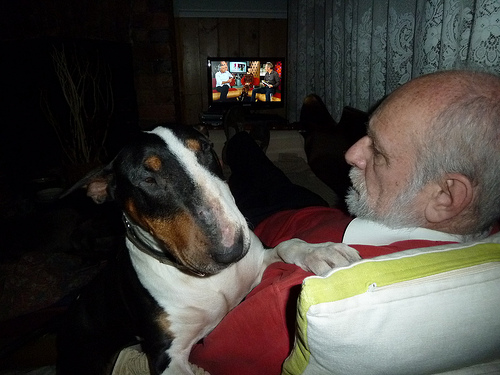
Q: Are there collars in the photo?
A: Yes, there is a collar.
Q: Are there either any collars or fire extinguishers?
A: Yes, there is a collar.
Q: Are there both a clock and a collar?
A: No, there is a collar but no clocks.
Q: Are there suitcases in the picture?
A: No, there are no suitcases.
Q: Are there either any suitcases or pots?
A: No, there are no suitcases or pots.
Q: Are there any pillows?
A: Yes, there is a pillow.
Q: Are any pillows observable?
A: Yes, there is a pillow.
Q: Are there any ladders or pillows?
A: Yes, there is a pillow.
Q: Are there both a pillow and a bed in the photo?
A: No, there is a pillow but no beds.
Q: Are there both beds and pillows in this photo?
A: No, there is a pillow but no beds.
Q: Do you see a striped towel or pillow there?
A: Yes, there is a striped pillow.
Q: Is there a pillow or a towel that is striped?
A: Yes, the pillow is striped.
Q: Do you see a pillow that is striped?
A: Yes, there is a striped pillow.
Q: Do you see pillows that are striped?
A: Yes, there is a pillow that is striped.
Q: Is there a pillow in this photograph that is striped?
A: Yes, there is a pillow that is striped.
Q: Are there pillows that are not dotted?
A: Yes, there is a striped pillow.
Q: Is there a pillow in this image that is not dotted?
A: Yes, there is a striped pillow.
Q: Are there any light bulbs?
A: No, there are no light bulbs.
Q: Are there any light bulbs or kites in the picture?
A: No, there are no light bulbs or kites.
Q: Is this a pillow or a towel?
A: This is a pillow.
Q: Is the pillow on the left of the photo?
A: No, the pillow is on the right of the image.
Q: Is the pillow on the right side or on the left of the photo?
A: The pillow is on the right of the image.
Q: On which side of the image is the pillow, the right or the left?
A: The pillow is on the right of the image.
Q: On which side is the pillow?
A: The pillow is on the right of the image.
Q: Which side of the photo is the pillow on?
A: The pillow is on the right of the image.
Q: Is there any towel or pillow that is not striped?
A: No, there is a pillow but it is striped.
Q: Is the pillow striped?
A: Yes, the pillow is striped.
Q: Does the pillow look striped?
A: Yes, the pillow is striped.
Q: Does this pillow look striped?
A: Yes, the pillow is striped.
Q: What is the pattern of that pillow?
A: The pillow is striped.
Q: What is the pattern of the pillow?
A: The pillow is striped.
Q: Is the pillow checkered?
A: No, the pillow is striped.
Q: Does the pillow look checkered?
A: No, the pillow is striped.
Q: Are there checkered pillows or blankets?
A: No, there is a pillow but it is striped.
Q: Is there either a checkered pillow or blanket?
A: No, there is a pillow but it is striped.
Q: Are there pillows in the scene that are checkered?
A: No, there is a pillow but it is striped.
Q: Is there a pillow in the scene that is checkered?
A: No, there is a pillow but it is striped.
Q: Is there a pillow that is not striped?
A: No, there is a pillow but it is striped.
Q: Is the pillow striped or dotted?
A: The pillow is striped.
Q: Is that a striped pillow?
A: Yes, that is a striped pillow.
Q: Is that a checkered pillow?
A: No, that is a striped pillow.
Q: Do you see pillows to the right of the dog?
A: Yes, there is a pillow to the right of the dog.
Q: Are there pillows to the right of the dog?
A: Yes, there is a pillow to the right of the dog.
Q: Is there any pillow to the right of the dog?
A: Yes, there is a pillow to the right of the dog.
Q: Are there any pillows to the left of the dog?
A: No, the pillow is to the right of the dog.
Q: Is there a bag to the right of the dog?
A: No, there is a pillow to the right of the dog.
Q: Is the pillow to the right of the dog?
A: Yes, the pillow is to the right of the dog.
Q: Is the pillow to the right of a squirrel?
A: No, the pillow is to the right of the dog.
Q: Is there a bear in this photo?
A: No, there are no bears.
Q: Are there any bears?
A: No, there are no bears.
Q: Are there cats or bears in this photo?
A: No, there are no bears or cats.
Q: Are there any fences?
A: No, there are no fences.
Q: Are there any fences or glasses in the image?
A: No, there are no fences or glasses.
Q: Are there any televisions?
A: Yes, there is a television.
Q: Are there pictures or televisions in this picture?
A: Yes, there is a television.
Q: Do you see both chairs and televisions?
A: No, there is a television but no chairs.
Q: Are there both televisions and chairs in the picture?
A: No, there is a television but no chairs.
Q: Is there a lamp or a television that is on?
A: Yes, the television is on.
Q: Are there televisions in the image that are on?
A: Yes, there is a television that is on.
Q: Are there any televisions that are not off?
A: Yes, there is a television that is on.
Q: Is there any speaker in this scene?
A: No, there are no speakers.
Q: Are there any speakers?
A: No, there are no speakers.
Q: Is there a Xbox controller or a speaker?
A: No, there are no speakers or Xbox controllers.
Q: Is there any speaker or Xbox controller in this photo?
A: No, there are no speakers or Xbox controllers.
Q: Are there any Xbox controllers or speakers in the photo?
A: No, there are no speakers or Xbox controllers.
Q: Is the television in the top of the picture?
A: Yes, the television is in the top of the image.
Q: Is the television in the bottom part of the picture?
A: No, the television is in the top of the image.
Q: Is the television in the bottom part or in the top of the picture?
A: The television is in the top of the image.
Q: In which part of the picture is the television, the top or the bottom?
A: The television is in the top of the image.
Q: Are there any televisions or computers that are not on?
A: No, there is a television but it is on.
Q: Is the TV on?
A: Yes, the TV is on.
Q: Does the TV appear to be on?
A: Yes, the TV is on.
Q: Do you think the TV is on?
A: Yes, the TV is on.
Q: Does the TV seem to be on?
A: Yes, the TV is on.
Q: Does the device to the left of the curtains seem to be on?
A: Yes, the TV is on.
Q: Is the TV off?
A: No, the TV is on.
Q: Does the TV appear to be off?
A: No, the TV is on.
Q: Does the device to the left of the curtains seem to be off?
A: No, the TV is on.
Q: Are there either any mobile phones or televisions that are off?
A: No, there is a television but it is on.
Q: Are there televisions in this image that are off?
A: No, there is a television but it is on.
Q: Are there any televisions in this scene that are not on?
A: No, there is a television but it is on.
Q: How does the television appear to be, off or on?
A: The television is on.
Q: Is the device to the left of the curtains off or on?
A: The television is on.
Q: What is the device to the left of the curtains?
A: The device is a television.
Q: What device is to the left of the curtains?
A: The device is a television.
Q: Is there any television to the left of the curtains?
A: Yes, there is a television to the left of the curtains.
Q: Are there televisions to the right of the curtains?
A: No, the television is to the left of the curtains.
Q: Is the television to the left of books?
A: No, the television is to the left of the curtains.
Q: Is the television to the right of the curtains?
A: No, the television is to the left of the curtains.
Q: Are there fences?
A: No, there are no fences.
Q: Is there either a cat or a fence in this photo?
A: No, there are no fences or cats.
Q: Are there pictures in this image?
A: No, there are no pictures.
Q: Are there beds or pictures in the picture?
A: No, there are no pictures or beds.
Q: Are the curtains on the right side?
A: Yes, the curtains are on the right of the image.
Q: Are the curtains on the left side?
A: No, the curtains are on the right of the image.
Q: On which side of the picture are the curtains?
A: The curtains are on the right of the image.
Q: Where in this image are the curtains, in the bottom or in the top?
A: The curtains are in the top of the image.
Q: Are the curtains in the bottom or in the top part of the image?
A: The curtains are in the top of the image.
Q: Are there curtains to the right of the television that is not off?
A: Yes, there are curtains to the right of the television.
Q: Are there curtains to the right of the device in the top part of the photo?
A: Yes, there are curtains to the right of the television.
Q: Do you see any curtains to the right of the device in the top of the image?
A: Yes, there are curtains to the right of the television.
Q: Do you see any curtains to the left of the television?
A: No, the curtains are to the right of the television.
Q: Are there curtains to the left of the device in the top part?
A: No, the curtains are to the right of the television.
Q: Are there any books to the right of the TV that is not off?
A: No, there are curtains to the right of the television.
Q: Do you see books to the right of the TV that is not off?
A: No, there are curtains to the right of the television.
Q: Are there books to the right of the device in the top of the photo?
A: No, there are curtains to the right of the television.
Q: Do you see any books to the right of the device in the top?
A: No, there are curtains to the right of the television.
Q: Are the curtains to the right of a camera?
A: No, the curtains are to the right of a television.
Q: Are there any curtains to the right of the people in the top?
A: Yes, there are curtains to the right of the people.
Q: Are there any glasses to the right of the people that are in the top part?
A: No, there are curtains to the right of the people.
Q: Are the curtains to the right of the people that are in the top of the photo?
A: Yes, the curtains are to the right of the people.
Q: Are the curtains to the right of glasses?
A: No, the curtains are to the right of the people.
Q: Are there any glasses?
A: No, there are no glasses.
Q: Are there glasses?
A: No, there are no glasses.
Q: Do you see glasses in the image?
A: No, there are no glasses.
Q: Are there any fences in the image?
A: No, there are no fences.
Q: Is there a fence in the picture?
A: No, there are no fences.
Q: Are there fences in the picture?
A: No, there are no fences.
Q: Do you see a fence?
A: No, there are no fences.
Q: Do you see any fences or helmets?
A: No, there are no fences or helmets.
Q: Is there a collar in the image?
A: Yes, there is a collar.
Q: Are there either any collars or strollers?
A: Yes, there is a collar.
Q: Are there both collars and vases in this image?
A: No, there is a collar but no vases.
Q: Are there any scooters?
A: No, there are no scooters.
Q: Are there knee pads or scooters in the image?
A: No, there are no scooters or knee pads.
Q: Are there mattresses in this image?
A: No, there are no mattresses.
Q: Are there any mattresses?
A: No, there are no mattresses.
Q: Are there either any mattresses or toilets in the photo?
A: No, there are no mattresses or toilets.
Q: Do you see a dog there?
A: Yes, there is a dog.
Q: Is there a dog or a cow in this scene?
A: Yes, there is a dog.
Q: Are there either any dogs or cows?
A: Yes, there is a dog.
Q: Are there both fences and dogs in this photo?
A: No, there is a dog but no fences.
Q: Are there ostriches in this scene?
A: No, there are no ostriches.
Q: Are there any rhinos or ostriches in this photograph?
A: No, there are no ostriches or rhinos.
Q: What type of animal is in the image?
A: The animal is a dog.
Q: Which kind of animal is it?
A: The animal is a dog.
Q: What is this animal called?
A: That is a dog.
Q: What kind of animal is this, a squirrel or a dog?
A: That is a dog.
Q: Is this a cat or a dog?
A: This is a dog.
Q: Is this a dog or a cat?
A: This is a dog.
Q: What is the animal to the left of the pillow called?
A: The animal is a dog.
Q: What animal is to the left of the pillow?
A: The animal is a dog.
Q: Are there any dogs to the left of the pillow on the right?
A: Yes, there is a dog to the left of the pillow.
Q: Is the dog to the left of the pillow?
A: Yes, the dog is to the left of the pillow.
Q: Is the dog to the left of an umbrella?
A: No, the dog is to the left of the pillow.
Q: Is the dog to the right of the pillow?
A: No, the dog is to the left of the pillow.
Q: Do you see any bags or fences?
A: No, there are no fences or bags.